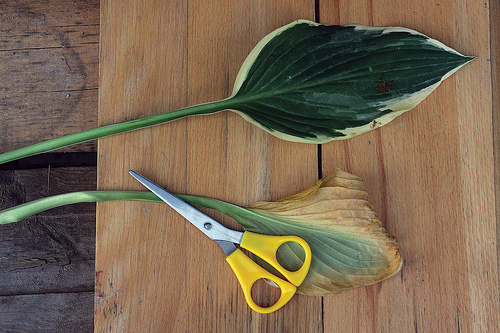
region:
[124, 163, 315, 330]
A yellow scissor on the table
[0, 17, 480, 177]
A green leaf on the table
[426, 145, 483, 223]
Part of the table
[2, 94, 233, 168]
The stem of the leaf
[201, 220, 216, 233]
The screw in the scissors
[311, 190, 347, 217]
The brown part of the leaf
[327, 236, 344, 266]
The green part of the leaf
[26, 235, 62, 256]
Part of the dark wood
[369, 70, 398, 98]
A brown spot on the leaf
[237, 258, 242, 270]
Part of the yellow scissor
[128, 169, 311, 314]
Pair of scissors on a table.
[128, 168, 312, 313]
Pair of scissors laying on a leaf.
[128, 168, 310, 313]
Pair of scissors with a yellow handle.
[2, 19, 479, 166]
A leaf laying face up on a table.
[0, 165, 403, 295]
A leaf laying face down on a table.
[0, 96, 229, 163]
Stem of a dark green leaf.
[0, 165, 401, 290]
A leaf lying under a pair of scissors.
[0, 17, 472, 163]
Dark green leaf on a table.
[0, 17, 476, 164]
Larger leaf on a table.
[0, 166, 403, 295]
Smaller leaf on a table.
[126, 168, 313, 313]
a pair of scissors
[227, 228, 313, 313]
yellow plastic scissor handles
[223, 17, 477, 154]
a dark green leaf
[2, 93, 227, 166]
a thick green stem of a leaf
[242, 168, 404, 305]
a dry shriveled leaf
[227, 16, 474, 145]
white edging on a green leaf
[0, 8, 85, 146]
a water spot on a wood plank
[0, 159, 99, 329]
a weather worn dark brown board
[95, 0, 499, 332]
two light brown boards holding leaves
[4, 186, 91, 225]
a white portion of a green stem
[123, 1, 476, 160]
The leaf is green.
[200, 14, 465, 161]
The edge of the leaf is yellow.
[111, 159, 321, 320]
The scissors are yellow.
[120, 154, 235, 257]
The edge is silver.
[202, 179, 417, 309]
The leaf is dead.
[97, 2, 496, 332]
The table is wood.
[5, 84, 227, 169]
The stem is green.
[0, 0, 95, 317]
The table is black.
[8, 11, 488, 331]
The scissors are on the leaf.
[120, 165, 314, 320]
a pair of scissors with a yellow handle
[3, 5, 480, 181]
a green leaf on a piece of wood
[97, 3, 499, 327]
a brown piece of wood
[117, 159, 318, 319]
scissors laying on a leaf and wood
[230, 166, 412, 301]
a leaf is turning brown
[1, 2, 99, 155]
a piece of wood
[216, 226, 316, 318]
yellow scissor handles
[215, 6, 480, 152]
a multicolored leaf lays on wood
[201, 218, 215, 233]
a metal screw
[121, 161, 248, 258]
the metal end of scissors